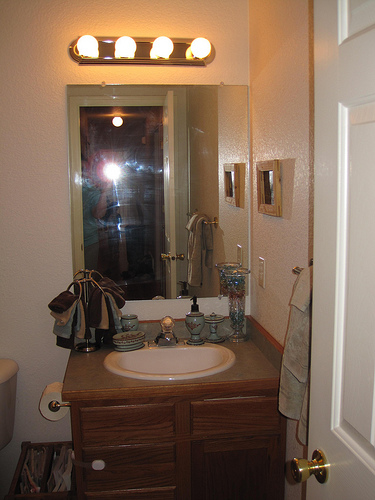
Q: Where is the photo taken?
A: Bathroom.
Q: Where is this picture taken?
A: Bathroom.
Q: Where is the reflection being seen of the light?
A: In the mirror.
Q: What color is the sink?
A: White.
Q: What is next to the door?
A: Towels.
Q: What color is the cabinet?
A: Brown.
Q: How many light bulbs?
A: Four.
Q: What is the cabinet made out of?
A: Wood.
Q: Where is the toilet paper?
A: Side of cabinet.